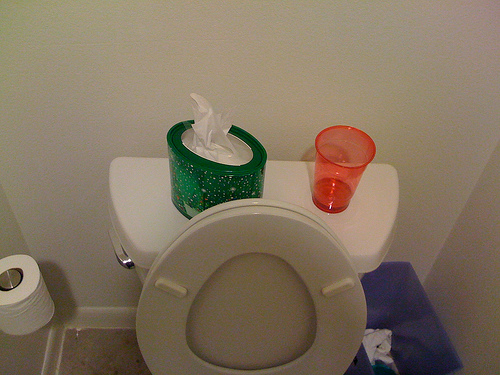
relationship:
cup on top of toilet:
[301, 124, 378, 221] [102, 148, 407, 374]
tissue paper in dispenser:
[178, 90, 256, 167] [158, 120, 269, 224]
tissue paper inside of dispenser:
[178, 90, 256, 167] [158, 120, 269, 224]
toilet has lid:
[102, 148, 407, 374] [99, 154, 405, 277]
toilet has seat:
[102, 148, 407, 374] [127, 188, 374, 375]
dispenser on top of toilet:
[158, 120, 269, 224] [102, 148, 407, 374]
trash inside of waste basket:
[361, 323, 407, 374] [343, 248, 468, 374]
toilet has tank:
[102, 148, 407, 374] [103, 151, 408, 313]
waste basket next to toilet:
[343, 248, 468, 374] [102, 148, 407, 374]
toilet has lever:
[102, 148, 407, 374] [107, 223, 134, 270]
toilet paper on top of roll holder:
[0, 250, 55, 343] [0, 267, 26, 288]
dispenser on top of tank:
[158, 120, 269, 224] [103, 151, 408, 313]